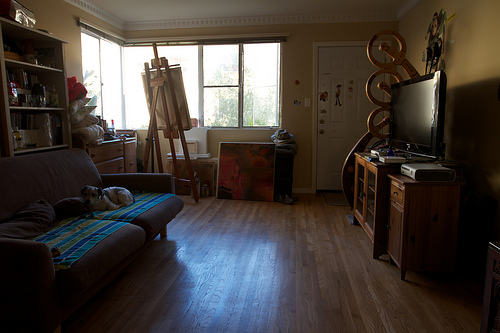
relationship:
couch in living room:
[0, 146, 188, 331] [1, 0, 499, 330]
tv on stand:
[380, 68, 448, 160] [344, 146, 413, 260]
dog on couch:
[80, 183, 135, 214] [0, 146, 188, 331]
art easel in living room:
[136, 42, 203, 206] [1, 0, 499, 330]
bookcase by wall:
[0, 15, 73, 150] [0, 0, 123, 140]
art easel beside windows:
[136, 42, 203, 206] [78, 22, 286, 129]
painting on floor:
[215, 138, 279, 205] [47, 193, 500, 333]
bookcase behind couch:
[0, 15, 73, 150] [0, 146, 188, 331]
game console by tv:
[377, 151, 406, 167] [380, 68, 448, 160]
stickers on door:
[318, 82, 359, 140] [312, 39, 398, 193]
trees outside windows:
[208, 63, 276, 125] [78, 22, 286, 129]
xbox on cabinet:
[397, 159, 456, 182] [382, 171, 460, 289]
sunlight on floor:
[176, 237, 276, 330] [47, 193, 500, 333]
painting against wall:
[215, 138, 279, 205] [124, 21, 400, 193]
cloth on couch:
[30, 187, 173, 271] [0, 146, 188, 331]